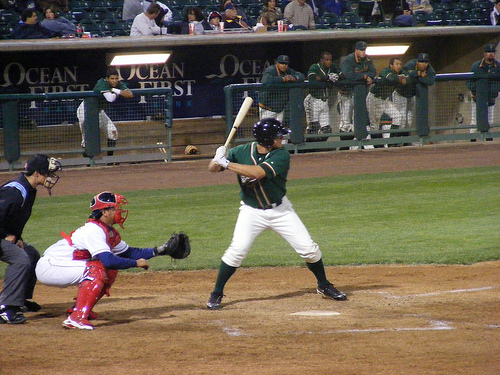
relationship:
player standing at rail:
[250, 43, 296, 137] [226, 74, 498, 148]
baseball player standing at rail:
[75, 64, 134, 161] [15, 88, 177, 158]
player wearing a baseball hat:
[259, 54, 306, 121] [270, 57, 291, 69]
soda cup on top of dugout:
[272, 17, 293, 33] [2, 30, 496, 171]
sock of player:
[299, 264, 337, 294] [195, 117, 347, 311]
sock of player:
[213, 259, 231, 295] [195, 117, 347, 311]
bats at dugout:
[147, 122, 178, 172] [38, 36, 475, 132]